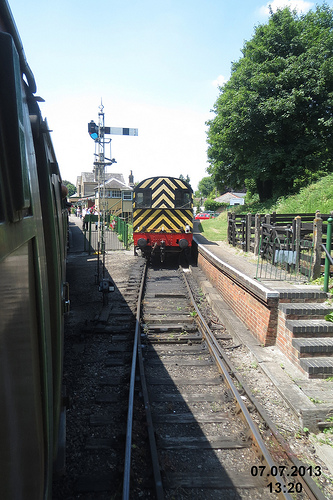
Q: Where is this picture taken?
A: A train station.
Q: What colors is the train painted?
A: Red, yellow, and black.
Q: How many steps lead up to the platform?
A: Four.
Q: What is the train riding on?
A: Train tracks.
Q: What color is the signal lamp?
A: Green.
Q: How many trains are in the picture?
A: Two.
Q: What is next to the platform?
A: A wooden fence.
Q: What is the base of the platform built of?
A: Bricks.